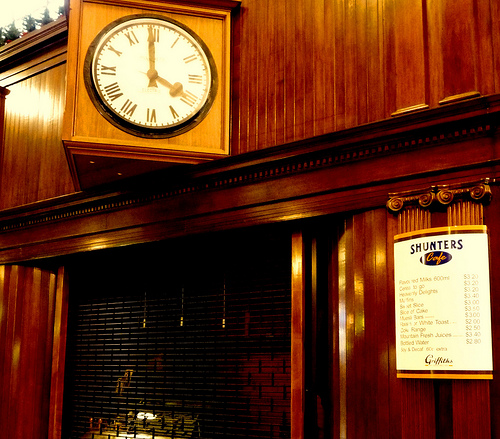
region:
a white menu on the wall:
[387, 216, 492, 388]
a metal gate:
[9, 235, 302, 437]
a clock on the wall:
[82, 26, 209, 145]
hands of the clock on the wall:
[139, 9, 213, 117]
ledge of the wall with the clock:
[0, 90, 493, 266]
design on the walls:
[382, 182, 491, 242]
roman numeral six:
[139, 97, 159, 133]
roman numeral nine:
[88, 62, 123, 79]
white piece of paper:
[387, 227, 492, 389]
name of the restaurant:
[404, 231, 474, 266]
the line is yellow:
[407, 371, 417, 388]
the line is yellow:
[407, 363, 419, 378]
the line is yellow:
[395, 369, 407, 399]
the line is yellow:
[411, 358, 419, 397]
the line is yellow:
[411, 365, 418, 387]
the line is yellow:
[404, 368, 419, 393]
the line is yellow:
[396, 368, 403, 385]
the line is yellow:
[402, 370, 409, 396]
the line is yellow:
[409, 369, 410, 392]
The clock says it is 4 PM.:
[62, 0, 233, 160]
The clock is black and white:
[56, 0, 243, 157]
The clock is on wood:
[56, 2, 248, 144]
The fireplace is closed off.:
[71, 271, 295, 437]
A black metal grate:
[58, 239, 290, 435]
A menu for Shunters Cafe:
[390, 217, 498, 384]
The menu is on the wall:
[387, 219, 498, 389]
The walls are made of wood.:
[236, 4, 498, 156]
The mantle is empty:
[1, 90, 498, 263]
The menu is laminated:
[380, 222, 499, 385]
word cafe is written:
[431, 253, 448, 260]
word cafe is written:
[427, 258, 449, 264]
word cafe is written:
[426, 249, 450, 276]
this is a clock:
[95, 22, 205, 115]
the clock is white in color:
[128, 51, 140, 83]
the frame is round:
[96, 11, 216, 123]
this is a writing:
[408, 239, 465, 251]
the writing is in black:
[410, 242, 463, 252]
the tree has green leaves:
[22, 15, 35, 28]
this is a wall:
[266, 18, 356, 62]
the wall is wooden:
[286, 40, 379, 80]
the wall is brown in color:
[278, 36, 355, 94]